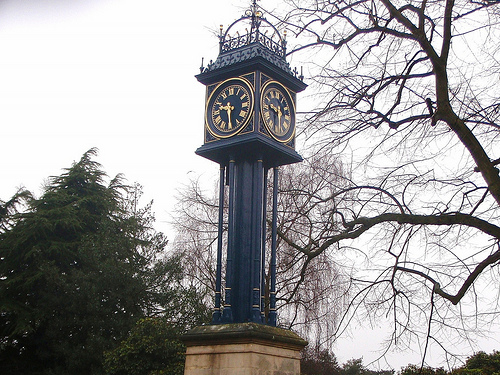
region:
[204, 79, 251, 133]
Gold and black face of the clock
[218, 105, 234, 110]
Hour hand on the clock face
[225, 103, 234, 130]
Minute hand on the clock face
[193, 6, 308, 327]
Black and gold clock tower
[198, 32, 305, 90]
Decorative top of clock tower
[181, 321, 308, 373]
Base stand of the clock tower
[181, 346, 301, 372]
Light brown base of clock tower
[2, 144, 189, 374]
green tree next to clock tower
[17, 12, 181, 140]
Cloudy skies over the clock tower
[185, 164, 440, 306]
Tree branches extending behind clock tower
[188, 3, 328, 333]
black clock tower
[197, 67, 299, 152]
two clocks on either side of the tower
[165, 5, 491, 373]
tree with no leaves on it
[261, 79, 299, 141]
gold and black clock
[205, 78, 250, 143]
clock indicating it's about 9:30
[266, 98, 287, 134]
two gold clock hands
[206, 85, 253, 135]
gold roman numerals around the clock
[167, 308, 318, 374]
pedestal under the clock tower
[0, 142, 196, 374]
thick, dark tree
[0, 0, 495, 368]
the sky is light gray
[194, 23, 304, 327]
this is a pole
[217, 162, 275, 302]
the pole is thick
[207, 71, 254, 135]
this is the clock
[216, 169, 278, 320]
the pole is black in color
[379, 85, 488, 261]
this is the tree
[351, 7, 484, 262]
the tree is branchy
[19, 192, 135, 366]
the trees are green in color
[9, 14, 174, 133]
this is the sky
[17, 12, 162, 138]
the sky is white in collor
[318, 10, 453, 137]
the branch is dry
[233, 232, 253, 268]
part of a pillar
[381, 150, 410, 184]
part of a branch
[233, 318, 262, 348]
edge of a line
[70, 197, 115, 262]
aprt of a tree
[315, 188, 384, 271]
part of a teree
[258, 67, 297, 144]
This is a big clock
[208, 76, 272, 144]
This is a big clock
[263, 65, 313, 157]
This is a big clock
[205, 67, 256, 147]
This is a big clock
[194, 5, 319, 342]
This is a big tower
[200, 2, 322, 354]
This is a big tower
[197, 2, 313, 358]
This is a big tower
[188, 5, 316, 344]
This is a big tower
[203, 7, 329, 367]
This is a big tower